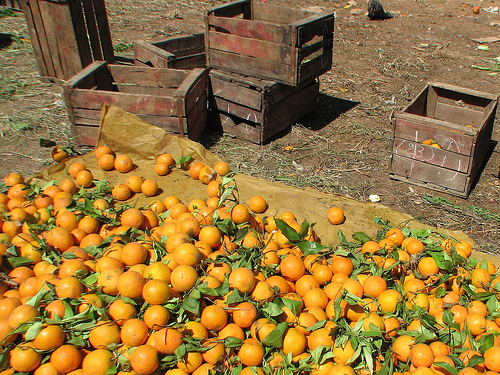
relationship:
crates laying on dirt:
[386, 77, 497, 199] [1, 0, 498, 259]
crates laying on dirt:
[201, 0, 336, 84] [1, 0, 498, 259]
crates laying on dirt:
[206, 65, 318, 146] [1, 0, 498, 259]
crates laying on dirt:
[61, 56, 211, 148] [1, 0, 498, 259]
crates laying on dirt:
[131, 27, 207, 71] [1, 0, 498, 259]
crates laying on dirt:
[19, 0, 116, 86] [1, 0, 498, 259]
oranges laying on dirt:
[2, 147, 497, 372] [1, 0, 498, 259]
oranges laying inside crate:
[193, 198, 327, 341] [382, 69, 484, 208]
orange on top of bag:
[243, 194, 268, 214] [6, 104, 496, 261]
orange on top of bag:
[278, 252, 303, 279] [6, 104, 496, 261]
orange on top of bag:
[376, 288, 401, 318] [6, 104, 496, 261]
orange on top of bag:
[237, 337, 264, 367] [6, 104, 496, 261]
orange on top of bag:
[135, 344, 157, 371] [6, 104, 496, 261]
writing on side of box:
[393, 129, 462, 182] [385, 79, 499, 200]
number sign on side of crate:
[216, 18, 277, 58] [202, 0, 335, 87]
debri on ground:
[368, 191, 380, 203] [304, 144, 381, 206]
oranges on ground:
[2, 147, 497, 372] [292, 123, 384, 183]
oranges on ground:
[275, 252, 405, 366] [230, 147, 433, 248]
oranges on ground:
[153, 148, 234, 200] [230, 147, 433, 248]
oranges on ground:
[45, 141, 158, 206] [230, 147, 433, 248]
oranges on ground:
[3, 207, 105, 256] [230, 147, 433, 248]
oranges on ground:
[5, 260, 89, 370] [230, 147, 433, 248]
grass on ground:
[417, 186, 448, 217] [2, 0, 497, 254]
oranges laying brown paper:
[107, 202, 271, 339] [260, 177, 297, 207]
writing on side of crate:
[394, 132, 465, 182] [383, 81, 499, 198]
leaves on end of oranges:
[1, 145, 499, 372] [2, 147, 497, 372]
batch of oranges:
[73, 242, 202, 307] [46, 190, 483, 364]